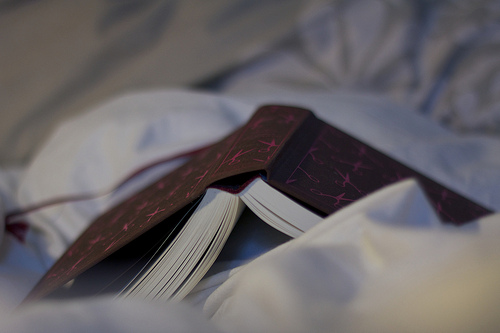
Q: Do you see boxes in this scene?
A: No, there are no boxes.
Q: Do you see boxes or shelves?
A: No, there are no boxes or shelves.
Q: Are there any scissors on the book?
A: Yes, there are scissors on the book.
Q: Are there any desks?
A: No, there are no desks.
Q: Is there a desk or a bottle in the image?
A: No, there are no desks or bottles.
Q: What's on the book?
A: The scissors are on the book.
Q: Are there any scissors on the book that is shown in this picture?
A: Yes, there are scissors on the book.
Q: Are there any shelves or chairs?
A: No, there are no chairs or shelves.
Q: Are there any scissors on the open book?
A: Yes, there are scissors on the book.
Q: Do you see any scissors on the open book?
A: Yes, there are scissors on the book.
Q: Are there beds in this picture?
A: Yes, there is a bed.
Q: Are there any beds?
A: Yes, there is a bed.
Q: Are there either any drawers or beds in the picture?
A: Yes, there is a bed.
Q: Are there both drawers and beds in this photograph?
A: No, there is a bed but no drawers.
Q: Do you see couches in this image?
A: No, there are no couches.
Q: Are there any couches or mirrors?
A: No, there are no couches or mirrors.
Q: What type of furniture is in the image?
A: The furniture is a bed.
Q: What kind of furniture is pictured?
A: The furniture is a bed.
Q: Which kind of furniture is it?
A: The piece of furniture is a bed.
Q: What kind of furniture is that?
A: That is a bed.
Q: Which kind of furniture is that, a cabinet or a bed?
A: That is a bed.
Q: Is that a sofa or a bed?
A: That is a bed.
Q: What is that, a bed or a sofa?
A: That is a bed.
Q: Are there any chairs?
A: No, there are no chairs.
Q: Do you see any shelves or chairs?
A: No, there are no chairs or shelves.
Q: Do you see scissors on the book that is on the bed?
A: Yes, there are scissors on the book.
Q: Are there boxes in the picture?
A: No, there are no boxes.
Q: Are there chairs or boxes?
A: No, there are no boxes or chairs.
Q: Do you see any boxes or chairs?
A: No, there are no boxes or chairs.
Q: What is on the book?
A: The scissors are on the book.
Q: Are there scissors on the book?
A: Yes, there are scissors on the book.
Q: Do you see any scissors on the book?
A: Yes, there are scissors on the book.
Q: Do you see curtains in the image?
A: No, there are no curtains.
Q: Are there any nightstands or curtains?
A: No, there are no curtains or nightstands.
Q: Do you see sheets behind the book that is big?
A: Yes, there is a sheet behind the book.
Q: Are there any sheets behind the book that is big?
A: Yes, there is a sheet behind the book.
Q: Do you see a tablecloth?
A: No, there are no tablecloths.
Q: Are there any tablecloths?
A: No, there are no tablecloths.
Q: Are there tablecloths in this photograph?
A: No, there are no tablecloths.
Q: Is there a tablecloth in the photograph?
A: No, there are no tablecloths.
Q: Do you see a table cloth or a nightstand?
A: No, there are no tablecloths or nightstands.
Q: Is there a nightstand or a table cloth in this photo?
A: No, there are no tablecloths or nightstands.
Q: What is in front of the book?
A: The sheet is in front of the book.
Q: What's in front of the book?
A: The sheet is in front of the book.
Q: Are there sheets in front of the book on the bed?
A: Yes, there is a sheet in front of the book.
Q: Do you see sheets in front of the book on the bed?
A: Yes, there is a sheet in front of the book.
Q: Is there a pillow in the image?
A: Yes, there is a pillow.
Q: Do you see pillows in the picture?
A: Yes, there is a pillow.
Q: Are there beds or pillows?
A: Yes, there is a pillow.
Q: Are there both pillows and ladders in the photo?
A: No, there is a pillow but no ladders.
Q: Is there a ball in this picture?
A: No, there are no balls.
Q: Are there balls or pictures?
A: No, there are no balls or pictures.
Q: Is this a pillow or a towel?
A: This is a pillow.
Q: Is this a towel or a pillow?
A: This is a pillow.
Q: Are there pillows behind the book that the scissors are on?
A: Yes, there is a pillow behind the book.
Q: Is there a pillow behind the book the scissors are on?
A: Yes, there is a pillow behind the book.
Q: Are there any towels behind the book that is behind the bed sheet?
A: No, there is a pillow behind the book.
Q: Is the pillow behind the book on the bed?
A: Yes, the pillow is behind the book.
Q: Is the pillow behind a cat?
A: No, the pillow is behind the book.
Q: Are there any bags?
A: No, there are no bags.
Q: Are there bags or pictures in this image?
A: No, there are no bags or pictures.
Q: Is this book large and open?
A: Yes, the book is large and open.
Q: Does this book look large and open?
A: Yes, the book is large and open.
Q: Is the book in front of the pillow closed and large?
A: No, the book is large but open.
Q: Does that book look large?
A: Yes, the book is large.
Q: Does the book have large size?
A: Yes, the book is large.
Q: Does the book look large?
A: Yes, the book is large.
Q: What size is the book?
A: The book is large.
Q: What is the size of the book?
A: The book is large.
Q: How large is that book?
A: The book is large.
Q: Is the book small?
A: No, the book is large.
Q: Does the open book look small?
A: No, the book is large.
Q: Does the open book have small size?
A: No, the book is large.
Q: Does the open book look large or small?
A: The book is large.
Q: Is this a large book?
A: Yes, this is a large book.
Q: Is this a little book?
A: No, this is a large book.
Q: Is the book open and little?
A: No, the book is open but large.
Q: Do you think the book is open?
A: Yes, the book is open.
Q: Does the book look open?
A: Yes, the book is open.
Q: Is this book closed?
A: No, the book is open.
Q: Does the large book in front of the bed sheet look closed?
A: No, the book is open.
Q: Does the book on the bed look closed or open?
A: The book is open.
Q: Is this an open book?
A: Yes, this is an open book.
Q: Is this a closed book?
A: No, this is an open book.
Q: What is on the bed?
A: The book is on the bed.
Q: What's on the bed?
A: The book is on the bed.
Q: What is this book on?
A: The book is on the bed.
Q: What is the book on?
A: The book is on the bed.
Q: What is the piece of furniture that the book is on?
A: The piece of furniture is a bed.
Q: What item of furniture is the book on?
A: The book is on the bed.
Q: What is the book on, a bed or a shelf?
A: The book is on a bed.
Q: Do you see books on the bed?
A: Yes, there is a book on the bed.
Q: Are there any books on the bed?
A: Yes, there is a book on the bed.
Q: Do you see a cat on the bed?
A: No, there is a book on the bed.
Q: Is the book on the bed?
A: Yes, the book is on the bed.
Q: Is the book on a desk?
A: No, the book is on the bed.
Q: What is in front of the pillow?
A: The book is in front of the pillow.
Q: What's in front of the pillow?
A: The book is in front of the pillow.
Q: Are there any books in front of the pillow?
A: Yes, there is a book in front of the pillow.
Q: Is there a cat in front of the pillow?
A: No, there is a book in front of the pillow.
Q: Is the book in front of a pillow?
A: Yes, the book is in front of a pillow.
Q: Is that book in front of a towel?
A: No, the book is in front of a pillow.